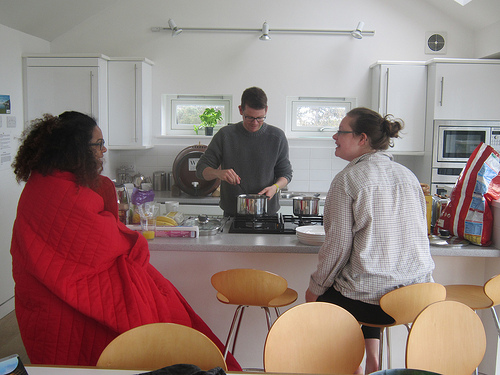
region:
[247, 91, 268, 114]
man has brown hair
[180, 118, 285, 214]
man has grey shirt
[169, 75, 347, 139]
white windows behind man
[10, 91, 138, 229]
woman has brown curly hair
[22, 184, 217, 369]
woman has large red blanket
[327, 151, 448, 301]
woman has white shirt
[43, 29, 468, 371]
picture taken inside a home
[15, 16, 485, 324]
people sitting around a kitchen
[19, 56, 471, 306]
women are sitting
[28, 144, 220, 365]
a woman wears a blanket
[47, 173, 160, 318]
the blanket is red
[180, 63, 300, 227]
a man is cooking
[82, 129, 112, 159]
the woman wears glasses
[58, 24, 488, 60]
the kitchen is white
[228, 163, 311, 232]
a man is stiring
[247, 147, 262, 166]
the man wears a gray shirt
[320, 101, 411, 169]
woman wearing eye glasses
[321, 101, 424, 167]
woman has hair in bun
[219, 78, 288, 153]
man wearing eye glasses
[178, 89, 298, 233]
man stirring silver pot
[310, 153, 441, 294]
woman wearing plaid shirt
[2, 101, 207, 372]
woman wrapped in blanket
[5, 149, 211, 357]
blanket is red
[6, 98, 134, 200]
woman has curly hair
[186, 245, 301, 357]
stool is light brown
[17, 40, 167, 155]
upper cabinet is white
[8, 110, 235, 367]
a woman wrapped in a red blanket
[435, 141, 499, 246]
a large snack bag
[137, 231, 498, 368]
stools in front of a counter-top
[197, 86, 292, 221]
man stirring something in a pot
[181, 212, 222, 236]
a silver colored pot lid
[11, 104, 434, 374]
two women smiling at each other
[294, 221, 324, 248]
stack of paper plates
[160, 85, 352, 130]
two windows behind man's head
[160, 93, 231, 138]
green potted plant on windowsill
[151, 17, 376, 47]
three lights on a track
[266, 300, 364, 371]
a light brown stool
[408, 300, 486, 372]
a light brown stool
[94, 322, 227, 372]
a light brown stool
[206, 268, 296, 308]
a light brown stool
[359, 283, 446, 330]
a light brown stool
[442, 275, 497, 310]
a light brown stool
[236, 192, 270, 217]
a metal cooking pot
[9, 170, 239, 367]
a re quilted blanket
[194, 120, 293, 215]
a long sleeve grey shirt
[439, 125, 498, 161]
a silver microwave oven